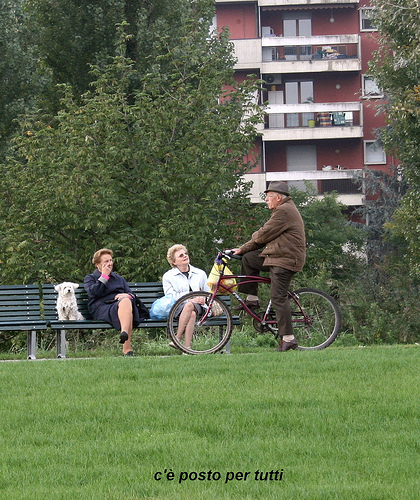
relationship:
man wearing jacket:
[231, 179, 308, 348] [237, 197, 304, 272]